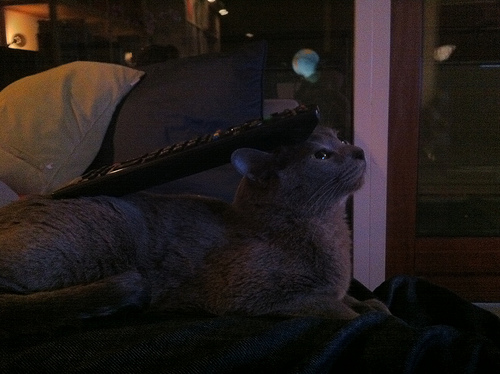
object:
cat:
[0, 124, 395, 334]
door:
[383, 0, 500, 305]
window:
[414, 0, 500, 238]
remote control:
[49, 103, 322, 201]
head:
[229, 115, 368, 219]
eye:
[314, 147, 332, 160]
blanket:
[0, 275, 500, 374]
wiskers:
[328, 181, 348, 204]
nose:
[352, 145, 365, 161]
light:
[3, 3, 53, 52]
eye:
[337, 137, 347, 145]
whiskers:
[311, 181, 343, 243]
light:
[322, 153, 328, 160]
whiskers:
[300, 176, 337, 205]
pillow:
[0, 60, 146, 199]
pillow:
[82, 42, 268, 205]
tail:
[0, 265, 145, 336]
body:
[0, 190, 352, 319]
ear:
[230, 147, 273, 188]